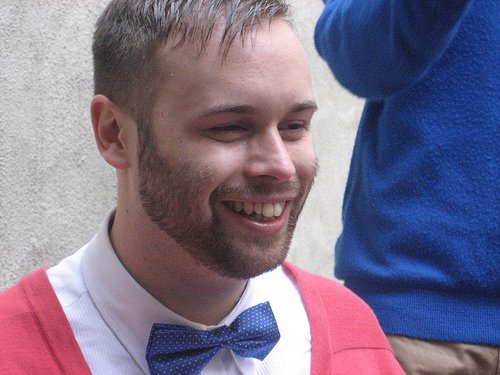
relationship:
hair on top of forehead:
[186, 13, 277, 69] [184, 21, 317, 108]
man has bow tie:
[2, 1, 409, 372] [147, 301, 281, 375]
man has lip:
[2, 1, 409, 372] [231, 206, 298, 232]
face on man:
[140, 18, 326, 288] [2, 1, 409, 372]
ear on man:
[90, 95, 127, 169] [0, 0, 406, 374]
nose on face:
[242, 122, 295, 184] [132, 18, 319, 281]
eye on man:
[197, 102, 258, 142] [2, 1, 409, 372]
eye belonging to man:
[278, 103, 318, 140] [2, 1, 409, 372]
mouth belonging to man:
[218, 194, 300, 234] [2, 1, 409, 372]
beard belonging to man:
[134, 119, 320, 280] [2, 1, 409, 372]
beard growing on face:
[134, 119, 320, 280] [132, 18, 319, 281]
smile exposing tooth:
[217, 194, 297, 234] [232, 200, 242, 212]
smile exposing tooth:
[217, 194, 297, 234] [242, 202, 252, 214]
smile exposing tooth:
[217, 194, 297, 234] [252, 201, 262, 215]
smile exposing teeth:
[217, 194, 297, 234] [261, 202, 274, 218]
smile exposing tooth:
[217, 194, 297, 234] [272, 203, 283, 215]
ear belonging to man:
[90, 95, 127, 169] [2, 1, 409, 372]